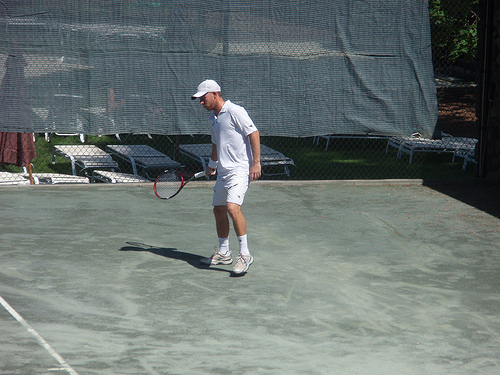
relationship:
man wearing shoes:
[188, 77, 264, 276] [201, 252, 252, 275]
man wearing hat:
[188, 77, 264, 276] [194, 76, 224, 96]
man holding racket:
[188, 77, 264, 276] [152, 167, 215, 200]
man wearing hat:
[188, 77, 264, 276] [185, 82, 223, 96]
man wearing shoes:
[188, 77, 264, 276] [200, 254, 259, 276]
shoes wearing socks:
[200, 254, 259, 276] [216, 227, 253, 256]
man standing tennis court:
[188, 77, 264, 276] [16, 116, 498, 346]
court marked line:
[8, 188, 498, 373] [1, 297, 75, 371]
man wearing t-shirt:
[188, 77, 264, 276] [202, 103, 252, 171]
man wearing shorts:
[188, 77, 264, 276] [211, 172, 250, 208]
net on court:
[2, 1, 443, 147] [0, 176, 500, 375]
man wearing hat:
[188, 77, 264, 276] [177, 62, 232, 106]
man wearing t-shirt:
[188, 73, 269, 280] [207, 98, 259, 181]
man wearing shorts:
[188, 77, 264, 276] [210, 156, 253, 214]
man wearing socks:
[188, 77, 264, 276] [217, 232, 249, 257]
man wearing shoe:
[188, 77, 264, 276] [202, 252, 232, 267]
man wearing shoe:
[188, 77, 264, 276] [231, 252, 253, 274]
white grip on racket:
[192, 170, 210, 179] [153, 165, 208, 203]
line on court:
[0, 294, 81, 374] [0, 161, 497, 370]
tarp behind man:
[1, 1, 498, 138] [188, 77, 264, 276]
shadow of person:
[118, 232, 206, 272] [157, 72, 266, 275]